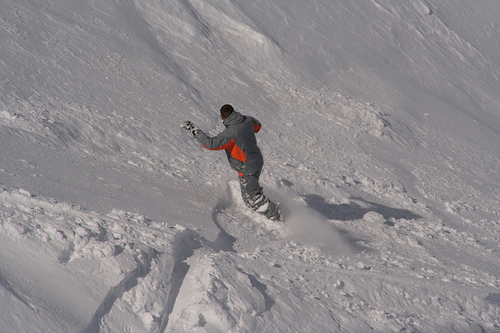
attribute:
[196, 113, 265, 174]
jacket — orange, grey